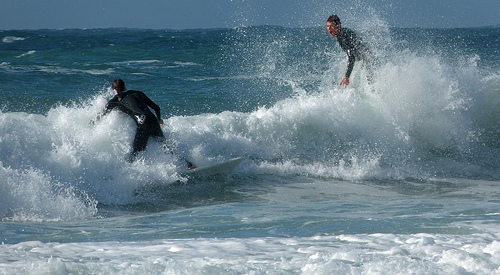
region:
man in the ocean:
[61, 55, 233, 202]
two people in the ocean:
[44, 3, 426, 231]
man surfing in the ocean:
[302, 8, 392, 98]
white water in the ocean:
[221, 235, 326, 270]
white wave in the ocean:
[37, 123, 116, 184]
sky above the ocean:
[46, 1, 127, 22]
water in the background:
[45, 17, 132, 62]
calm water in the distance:
[60, 25, 125, 52]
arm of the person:
[320, 35, 355, 107]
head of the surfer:
[100, 63, 140, 98]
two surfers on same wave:
[68, 7, 382, 184]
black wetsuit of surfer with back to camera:
[89, 67, 190, 172]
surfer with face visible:
[314, 15, 381, 94]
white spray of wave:
[6, 2, 491, 221]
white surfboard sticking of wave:
[175, 149, 250, 174]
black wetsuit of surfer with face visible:
[342, 25, 382, 86]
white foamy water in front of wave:
[20, 207, 495, 264]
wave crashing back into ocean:
[9, 54, 488, 218]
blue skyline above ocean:
[4, 5, 499, 30]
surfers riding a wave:
[85, 7, 412, 182]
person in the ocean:
[63, 49, 240, 204]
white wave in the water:
[244, 78, 401, 165]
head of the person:
[312, 5, 354, 45]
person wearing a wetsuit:
[91, 43, 201, 160]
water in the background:
[70, 13, 147, 54]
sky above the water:
[51, 2, 136, 27]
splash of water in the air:
[201, 15, 313, 72]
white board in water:
[190, 141, 260, 190]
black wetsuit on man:
[104, 82, 176, 153]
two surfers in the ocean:
[68, 11, 384, 208]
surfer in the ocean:
[68, 44, 213, 248]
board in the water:
[184, 122, 248, 189]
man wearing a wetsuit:
[66, 49, 206, 179]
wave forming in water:
[243, 92, 317, 170]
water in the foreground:
[240, 213, 330, 268]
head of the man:
[309, 5, 354, 57]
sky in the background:
[120, 3, 164, 28]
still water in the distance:
[77, 28, 114, 55]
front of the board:
[211, 145, 253, 190]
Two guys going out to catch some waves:
[61, 2, 420, 177]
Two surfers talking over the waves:
[87, 9, 394, 184]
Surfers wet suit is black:
[80, 65, 242, 196]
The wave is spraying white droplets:
[47, 147, 178, 187]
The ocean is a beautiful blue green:
[183, 37, 217, 104]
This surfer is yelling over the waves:
[313, 6, 358, 92]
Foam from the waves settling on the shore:
[285, 205, 370, 272]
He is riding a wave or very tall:
[305, 3, 425, 133]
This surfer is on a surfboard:
[68, 62, 243, 222]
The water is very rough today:
[113, 11, 255, 76]